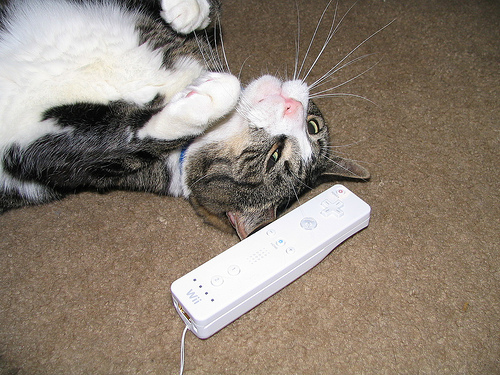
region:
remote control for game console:
[164, 187, 375, 343]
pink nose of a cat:
[281, 92, 304, 117]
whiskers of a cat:
[295, 5, 390, 99]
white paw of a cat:
[151, 77, 247, 146]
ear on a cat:
[321, 147, 376, 185]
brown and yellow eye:
[305, 116, 320, 136]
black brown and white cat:
[1, 5, 365, 246]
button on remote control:
[299, 216, 319, 234]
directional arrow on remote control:
[319, 193, 349, 220]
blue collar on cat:
[176, 147, 191, 195]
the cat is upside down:
[2, 2, 368, 241]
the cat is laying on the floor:
[5, 5, 343, 255]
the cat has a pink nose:
[283, 94, 298, 116]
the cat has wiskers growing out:
[297, 28, 380, 104]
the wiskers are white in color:
[290, 33, 387, 106]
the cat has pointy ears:
[319, 141, 374, 181]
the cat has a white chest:
[0, 0, 181, 122]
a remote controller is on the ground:
[171, 179, 369, 335]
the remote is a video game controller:
[167, 179, 367, 339]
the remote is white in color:
[173, 177, 370, 337]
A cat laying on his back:
[4, 6, 449, 301]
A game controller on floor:
[159, 178, 384, 336]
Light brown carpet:
[346, 267, 465, 352]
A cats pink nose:
[275, 83, 306, 125]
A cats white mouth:
[245, 71, 317, 133]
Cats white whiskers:
[282, 12, 375, 102]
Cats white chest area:
[17, 10, 158, 110]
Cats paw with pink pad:
[174, 67, 221, 106]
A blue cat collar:
[171, 142, 199, 187]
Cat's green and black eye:
[261, 130, 282, 177]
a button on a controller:
[297, 215, 320, 235]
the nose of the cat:
[280, 93, 305, 120]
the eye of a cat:
[305, 110, 320, 135]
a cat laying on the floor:
[0, 0, 375, 240]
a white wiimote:
[165, 180, 370, 330]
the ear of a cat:
[320, 151, 370, 184]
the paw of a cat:
[158, 70, 239, 142]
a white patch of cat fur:
[11, 6, 123, 92]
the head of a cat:
[185, 73, 331, 237]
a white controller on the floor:
[166, 179, 376, 339]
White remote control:
[170, 175, 399, 346]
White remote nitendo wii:
[163, 188, 387, 341]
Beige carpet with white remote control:
[181, 188, 413, 349]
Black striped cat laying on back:
[0, 8, 393, 233]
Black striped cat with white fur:
[3, 3, 328, 223]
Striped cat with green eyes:
[190, 51, 335, 222]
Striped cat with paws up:
[18, 5, 338, 245]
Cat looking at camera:
[15, 2, 327, 237]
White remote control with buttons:
[160, 175, 402, 348]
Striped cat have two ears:
[21, 13, 350, 235]